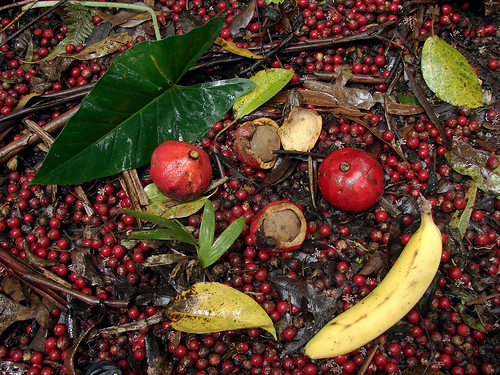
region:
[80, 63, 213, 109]
Large green leaf on ground.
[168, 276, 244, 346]
Yellow leaf on ground.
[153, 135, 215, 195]
Red nut laying on ground.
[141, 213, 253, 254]
Green leaves laying on ground.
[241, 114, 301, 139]
Cracked open nut laying on ground.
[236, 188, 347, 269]
Cracked open nut laying on ground.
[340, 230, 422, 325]
Yellow banana laying on ground.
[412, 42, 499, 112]
Green leaf laying on ground.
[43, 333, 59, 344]
Red berries laying on ground.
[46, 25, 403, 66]
Brown twigs laying on ground.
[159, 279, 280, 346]
yellow leaf with stem end starting to die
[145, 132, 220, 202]
pomegranate laying on leaves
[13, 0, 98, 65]
single fern branch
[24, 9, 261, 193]
large heart shaped green leaf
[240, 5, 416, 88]
twigs laying on cranberries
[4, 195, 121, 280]
cranberries laying on ground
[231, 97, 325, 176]
red pomegranate broke in half and hollowed out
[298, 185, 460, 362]
banana laying on cranberries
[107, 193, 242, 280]
plant growing up through ground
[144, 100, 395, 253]
pomegranates laying on cranberries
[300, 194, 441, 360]
the banana that hasn't been peeled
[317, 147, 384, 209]
the pomegranate on the ground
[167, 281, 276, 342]
the leaf near the banana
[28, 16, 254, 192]
the big green leaf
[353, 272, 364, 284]
the cranberry on the ground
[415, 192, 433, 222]
the stem of the banana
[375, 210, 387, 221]
the cranberry on the ground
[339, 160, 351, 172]
the stem on the pomegranate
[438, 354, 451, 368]
the cranberry on the ground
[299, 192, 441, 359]
the brown marks on the banana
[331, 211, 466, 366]
the banana is yellow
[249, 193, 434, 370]
the banana is yellow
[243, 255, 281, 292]
the red coffee ground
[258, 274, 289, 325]
the red coffee ground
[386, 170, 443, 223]
the red coffee ground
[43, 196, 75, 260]
the red coffee ground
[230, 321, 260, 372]
the red coffee ground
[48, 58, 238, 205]
a big green leaf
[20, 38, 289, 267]
a big green leaf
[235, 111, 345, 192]
fruit's skin is starting to rot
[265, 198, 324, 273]
fruit's skin is starting to rot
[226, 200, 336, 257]
fruit's skin is starting to rot